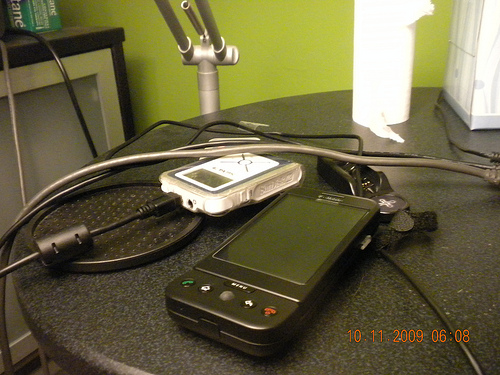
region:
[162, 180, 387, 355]
black cellphone on table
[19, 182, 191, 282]
charger connected to electronic device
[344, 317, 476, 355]
date when picture was taken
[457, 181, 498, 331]
black table where electronics are on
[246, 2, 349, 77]
green painted wall in the background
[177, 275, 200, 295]
green call button on phone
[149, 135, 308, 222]
electronic device on a table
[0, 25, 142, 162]
cabinet in the corner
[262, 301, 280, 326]
red end button on phone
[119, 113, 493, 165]
wires on a table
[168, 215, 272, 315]
the phone is black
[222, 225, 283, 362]
the phone is black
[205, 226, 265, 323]
the phone is black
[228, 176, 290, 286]
the phone is black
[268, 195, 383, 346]
the phone is black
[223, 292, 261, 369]
the phone is black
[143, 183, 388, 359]
bulky black cellphone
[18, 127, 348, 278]
white electronic device is plugged in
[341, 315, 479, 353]
photo time stamp reads October 11, 2009 06:08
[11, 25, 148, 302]
several cords on the table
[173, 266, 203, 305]
green circular call button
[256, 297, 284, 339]
red circular end call button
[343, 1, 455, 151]
roll of paper towels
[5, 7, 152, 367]
black and white cabinet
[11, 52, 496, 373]
black circular table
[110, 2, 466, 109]
lime green wall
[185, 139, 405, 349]
the phone is black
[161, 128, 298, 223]
the object is white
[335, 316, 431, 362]
picture taken on 10/11/2009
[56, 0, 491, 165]
the wall is green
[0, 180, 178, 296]
the cord is black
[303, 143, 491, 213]
the cord is gray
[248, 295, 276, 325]
red button on phone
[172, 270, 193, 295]
green button on phone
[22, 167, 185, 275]
round object under cord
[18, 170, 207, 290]
round object is black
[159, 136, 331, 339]
a phone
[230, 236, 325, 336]
a phone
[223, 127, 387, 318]
a phone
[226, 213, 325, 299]
a phone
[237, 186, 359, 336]
a phone